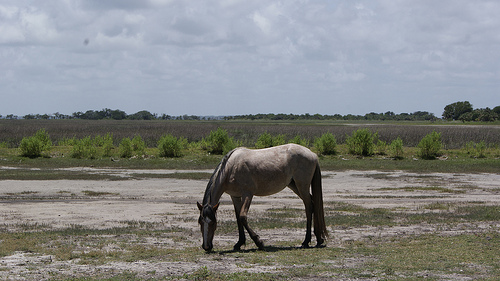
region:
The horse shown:
[187, 144, 334, 252]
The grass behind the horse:
[0, 113, 495, 174]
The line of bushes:
[16, 118, 496, 160]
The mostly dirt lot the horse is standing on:
[0, 161, 497, 280]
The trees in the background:
[0, 96, 498, 121]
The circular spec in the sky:
[78, 33, 95, 49]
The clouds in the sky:
[0, 0, 498, 115]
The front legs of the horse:
[227, 193, 267, 250]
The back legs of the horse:
[293, 187, 320, 249]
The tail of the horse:
[313, 167, 333, 239]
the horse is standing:
[170, 127, 340, 252]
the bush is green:
[28, 121, 160, 169]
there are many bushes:
[22, 119, 208, 158]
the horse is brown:
[177, 124, 344, 256]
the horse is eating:
[177, 125, 335, 256]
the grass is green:
[37, 225, 119, 265]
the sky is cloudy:
[105, 17, 255, 92]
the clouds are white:
[85, 5, 254, 92]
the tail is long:
[287, 147, 338, 243]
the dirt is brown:
[99, 170, 169, 201]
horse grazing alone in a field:
[106, 110, 388, 272]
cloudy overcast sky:
[4, 3, 499, 122]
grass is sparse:
[3, 162, 498, 279]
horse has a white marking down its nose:
[194, 209, 220, 254]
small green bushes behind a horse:
[10, 124, 499, 164]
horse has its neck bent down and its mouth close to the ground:
[188, 142, 333, 258]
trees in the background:
[3, 96, 498, 123]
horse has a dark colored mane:
[198, 140, 244, 223]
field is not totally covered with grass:
[3, 160, 498, 275]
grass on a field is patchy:
[6, 152, 499, 277]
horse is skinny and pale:
[168, 122, 336, 260]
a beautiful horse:
[182, 107, 372, 259]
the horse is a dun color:
[191, 140, 341, 252]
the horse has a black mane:
[194, 134, 231, 270]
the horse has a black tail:
[306, 148, 348, 248]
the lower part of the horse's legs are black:
[227, 210, 331, 250]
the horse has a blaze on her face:
[191, 191, 231, 260]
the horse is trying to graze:
[20, 166, 441, 275]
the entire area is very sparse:
[13, 124, 473, 274]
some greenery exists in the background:
[63, 125, 227, 170]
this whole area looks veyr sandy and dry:
[58, 174, 145, 220]